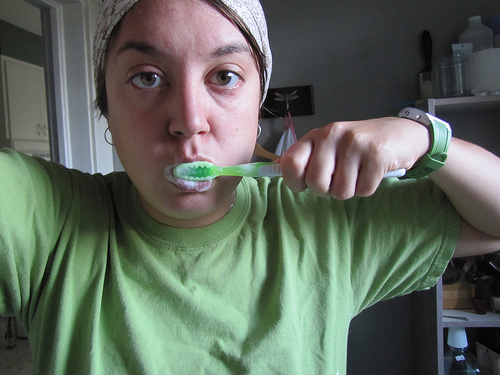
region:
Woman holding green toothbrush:
[0, 0, 498, 374]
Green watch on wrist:
[391, 105, 453, 180]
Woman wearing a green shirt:
[0, 0, 497, 374]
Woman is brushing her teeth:
[0, 0, 498, 374]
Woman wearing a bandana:
[0, 0, 499, 374]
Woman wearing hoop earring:
[0, 0, 498, 374]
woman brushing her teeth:
[0, 0, 497, 372]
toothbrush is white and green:
[169, 157, 408, 183]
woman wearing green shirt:
[3, 0, 498, 372]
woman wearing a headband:
[1, 2, 498, 374]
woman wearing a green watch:
[3, 2, 498, 374]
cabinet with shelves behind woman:
[403, 88, 498, 374]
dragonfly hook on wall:
[258, 83, 313, 118]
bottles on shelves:
[413, 15, 498, 374]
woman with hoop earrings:
[0, 1, 499, 373]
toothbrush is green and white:
[173, 160, 406, 181]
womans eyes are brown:
[127, 70, 172, 90]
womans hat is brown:
[93, 0, 273, 105]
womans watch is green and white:
[396, 106, 450, 179]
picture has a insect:
[262, 85, 314, 116]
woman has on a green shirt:
[4, 147, 461, 373]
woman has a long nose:
[171, 64, 208, 136]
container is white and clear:
[459, 14, 493, 49]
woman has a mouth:
[166, 156, 221, 190]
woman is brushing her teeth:
[2, 3, 499, 373]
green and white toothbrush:
[169, 158, 408, 181]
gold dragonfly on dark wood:
[257, 80, 317, 119]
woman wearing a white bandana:
[0, 0, 498, 373]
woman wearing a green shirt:
[0, 1, 498, 373]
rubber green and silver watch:
[394, 103, 454, 183]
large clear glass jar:
[429, 50, 472, 100]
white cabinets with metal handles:
[1, 57, 49, 144]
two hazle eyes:
[126, 63, 242, 89]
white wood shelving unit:
[414, 88, 499, 374]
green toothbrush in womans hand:
[173, 161, 288, 183]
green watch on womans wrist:
[396, 105, 451, 180]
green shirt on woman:
[2, 144, 462, 374]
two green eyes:
[128, 65, 241, 92]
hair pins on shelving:
[445, 310, 467, 322]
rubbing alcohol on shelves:
[455, 11, 497, 92]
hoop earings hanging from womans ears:
[103, 125, 260, 145]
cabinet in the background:
[1, 55, 55, 157]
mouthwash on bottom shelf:
[446, 325, 479, 373]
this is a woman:
[23, 5, 473, 370]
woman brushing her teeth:
[11, 6, 486, 371]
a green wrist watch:
[370, 60, 465, 195]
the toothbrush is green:
[135, 140, 285, 200]